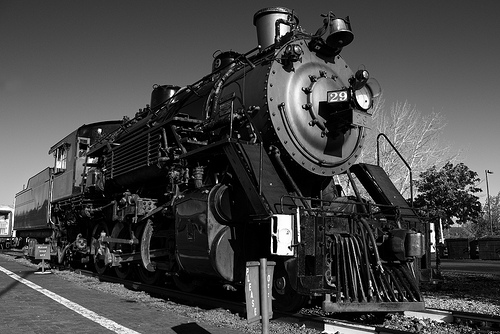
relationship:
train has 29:
[62, 34, 458, 323] [325, 90, 350, 104]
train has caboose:
[12, 7, 430, 323] [11, 165, 53, 255]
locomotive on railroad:
[0, 3, 440, 331] [1, 223, 498, 332]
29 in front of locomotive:
[325, 90, 350, 104] [0, 3, 440, 331]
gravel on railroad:
[319, 314, 489, 331] [129, 256, 498, 328]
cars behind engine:
[6, 134, 140, 255] [204, 33, 472, 268]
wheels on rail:
[4, 232, 146, 292] [317, 307, 496, 331]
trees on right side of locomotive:
[364, 102, 484, 266] [0, 3, 440, 331]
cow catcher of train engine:
[301, 216, 471, 331] [15, 3, 425, 311]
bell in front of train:
[319, 15, 359, 52] [12, 7, 430, 323]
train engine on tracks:
[15, 3, 425, 311] [298, 306, 498, 332]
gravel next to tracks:
[431, 288, 483, 330] [289, 285, 474, 332]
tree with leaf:
[405, 158, 477, 269] [466, 167, 473, 176]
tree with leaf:
[405, 158, 477, 269] [449, 196, 456, 203]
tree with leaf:
[405, 158, 477, 269] [425, 168, 433, 177]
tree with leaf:
[405, 158, 477, 269] [420, 198, 432, 207]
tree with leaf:
[405, 158, 477, 269] [470, 212, 478, 221]